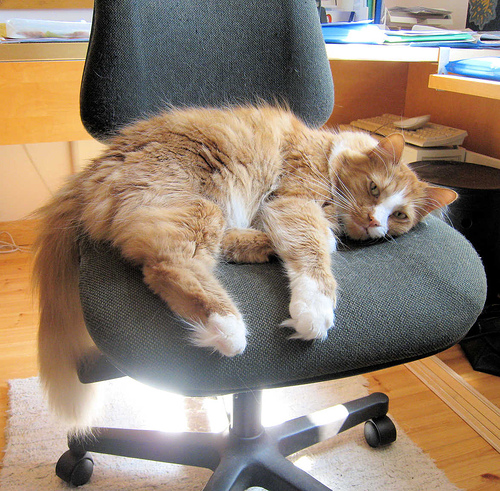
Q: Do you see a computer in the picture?
A: Yes, there is a computer.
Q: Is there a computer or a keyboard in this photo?
A: Yes, there is a computer.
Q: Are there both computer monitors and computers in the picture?
A: No, there is a computer but no computer monitors.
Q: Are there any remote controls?
A: No, there are no remote controls.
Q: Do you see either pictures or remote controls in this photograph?
A: No, there are no remote controls or pictures.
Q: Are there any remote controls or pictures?
A: No, there are no remote controls or pictures.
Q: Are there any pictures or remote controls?
A: No, there are no remote controls or pictures.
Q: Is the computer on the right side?
A: Yes, the computer is on the right of the image.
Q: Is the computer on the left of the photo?
A: No, the computer is on the right of the image.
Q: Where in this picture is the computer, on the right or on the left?
A: The computer is on the right of the image.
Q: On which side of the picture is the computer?
A: The computer is on the right of the image.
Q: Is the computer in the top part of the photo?
A: Yes, the computer is in the top of the image.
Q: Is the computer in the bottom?
A: No, the computer is in the top of the image.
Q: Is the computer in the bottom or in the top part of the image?
A: The computer is in the top of the image.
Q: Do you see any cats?
A: Yes, there is a cat.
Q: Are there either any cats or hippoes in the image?
A: Yes, there is a cat.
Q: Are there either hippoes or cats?
A: Yes, there is a cat.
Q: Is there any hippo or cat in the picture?
A: Yes, there is a cat.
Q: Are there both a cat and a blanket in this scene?
A: No, there is a cat but no blankets.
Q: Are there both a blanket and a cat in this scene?
A: No, there is a cat but no blankets.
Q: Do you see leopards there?
A: No, there are no leopards.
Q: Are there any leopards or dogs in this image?
A: No, there are no leopards or dogs.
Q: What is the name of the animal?
A: The animal is a cat.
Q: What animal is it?
A: The animal is a cat.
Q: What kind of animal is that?
A: This is a cat.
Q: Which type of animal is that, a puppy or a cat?
A: This is a cat.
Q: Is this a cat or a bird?
A: This is a cat.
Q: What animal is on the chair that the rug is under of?
A: The cat is on the chair.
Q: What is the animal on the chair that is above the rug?
A: The animal is a cat.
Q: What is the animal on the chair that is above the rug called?
A: The animal is a cat.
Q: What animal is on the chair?
A: The animal is a cat.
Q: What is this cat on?
A: The cat is on the chair.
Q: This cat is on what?
A: The cat is on the chair.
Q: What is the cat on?
A: The cat is on the chair.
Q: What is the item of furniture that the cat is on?
A: The piece of furniture is a chair.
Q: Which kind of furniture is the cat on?
A: The cat is on the chair.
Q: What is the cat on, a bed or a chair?
A: The cat is on a chair.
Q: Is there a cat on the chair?
A: Yes, there is a cat on the chair.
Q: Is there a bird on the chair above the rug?
A: No, there is a cat on the chair.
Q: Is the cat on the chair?
A: Yes, the cat is on the chair.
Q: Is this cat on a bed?
A: No, the cat is on the chair.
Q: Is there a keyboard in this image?
A: Yes, there is a keyboard.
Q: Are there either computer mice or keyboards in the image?
A: Yes, there is a keyboard.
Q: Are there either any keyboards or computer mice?
A: Yes, there is a keyboard.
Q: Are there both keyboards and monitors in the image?
A: No, there is a keyboard but no monitors.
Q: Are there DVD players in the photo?
A: No, there are no DVD players.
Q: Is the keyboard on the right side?
A: Yes, the keyboard is on the right of the image.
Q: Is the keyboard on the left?
A: No, the keyboard is on the right of the image.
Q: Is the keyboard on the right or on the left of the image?
A: The keyboard is on the right of the image.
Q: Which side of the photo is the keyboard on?
A: The keyboard is on the right of the image.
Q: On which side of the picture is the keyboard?
A: The keyboard is on the right of the image.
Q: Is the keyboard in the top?
A: Yes, the keyboard is in the top of the image.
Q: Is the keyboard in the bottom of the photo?
A: No, the keyboard is in the top of the image.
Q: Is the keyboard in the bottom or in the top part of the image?
A: The keyboard is in the top of the image.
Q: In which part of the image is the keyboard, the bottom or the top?
A: The keyboard is in the top of the image.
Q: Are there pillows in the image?
A: No, there are no pillows.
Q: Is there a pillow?
A: No, there are no pillows.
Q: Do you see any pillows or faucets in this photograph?
A: No, there are no pillows or faucets.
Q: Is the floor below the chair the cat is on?
A: Yes, the floor is below the chair.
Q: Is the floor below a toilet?
A: No, the floor is below the chair.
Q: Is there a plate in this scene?
A: No, there are no plates.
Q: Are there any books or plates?
A: No, there are no plates or books.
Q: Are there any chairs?
A: Yes, there is a chair.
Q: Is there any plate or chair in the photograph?
A: Yes, there is a chair.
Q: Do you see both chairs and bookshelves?
A: No, there is a chair but no bookshelves.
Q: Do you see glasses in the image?
A: No, there are no glasses.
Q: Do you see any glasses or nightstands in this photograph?
A: No, there are no glasses or nightstands.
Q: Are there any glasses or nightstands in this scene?
A: No, there are no glasses or nightstands.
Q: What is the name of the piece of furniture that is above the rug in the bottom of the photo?
A: The piece of furniture is a chair.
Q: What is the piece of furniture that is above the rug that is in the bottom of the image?
A: The piece of furniture is a chair.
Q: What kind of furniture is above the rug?
A: The piece of furniture is a chair.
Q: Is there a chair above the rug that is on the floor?
A: Yes, there is a chair above the rug.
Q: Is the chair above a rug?
A: Yes, the chair is above a rug.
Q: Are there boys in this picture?
A: No, there are no boys.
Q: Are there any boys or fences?
A: No, there are no boys or fences.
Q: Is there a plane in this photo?
A: No, there are no airplanes.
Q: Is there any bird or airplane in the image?
A: No, there are no airplanes or birds.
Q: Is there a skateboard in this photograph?
A: No, there are no skateboards.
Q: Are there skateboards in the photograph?
A: No, there are no skateboards.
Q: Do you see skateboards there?
A: No, there are no skateboards.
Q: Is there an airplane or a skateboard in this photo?
A: No, there are no skateboards or airplanes.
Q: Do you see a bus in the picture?
A: No, there are no buses.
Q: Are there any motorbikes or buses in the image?
A: No, there are no buses or motorbikes.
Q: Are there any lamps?
A: No, there are no lamps.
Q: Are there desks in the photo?
A: Yes, there is a desk.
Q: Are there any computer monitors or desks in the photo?
A: Yes, there is a desk.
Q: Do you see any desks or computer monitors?
A: Yes, there is a desk.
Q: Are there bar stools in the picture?
A: No, there are no bar stools.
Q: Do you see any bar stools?
A: No, there are no bar stools.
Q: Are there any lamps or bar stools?
A: No, there are no bar stools or lamps.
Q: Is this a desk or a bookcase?
A: This is a desk.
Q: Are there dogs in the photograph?
A: No, there are no dogs.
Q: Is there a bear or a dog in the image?
A: No, there are no dogs or bears.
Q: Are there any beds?
A: No, there are no beds.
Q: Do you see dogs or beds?
A: No, there are no beds or dogs.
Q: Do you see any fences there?
A: No, there are no fences.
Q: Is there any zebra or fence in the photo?
A: No, there are no fences or zebras.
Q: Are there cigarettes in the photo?
A: No, there are no cigarettes.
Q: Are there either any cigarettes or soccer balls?
A: No, there are no cigarettes or soccer balls.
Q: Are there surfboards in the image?
A: No, there are no surfboards.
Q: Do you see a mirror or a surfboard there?
A: No, there are no surfboards or mirrors.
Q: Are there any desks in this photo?
A: Yes, there is a desk.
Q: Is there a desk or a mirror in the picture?
A: Yes, there is a desk.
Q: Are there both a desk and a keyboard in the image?
A: Yes, there are both a desk and a keyboard.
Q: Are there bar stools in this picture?
A: No, there are no bar stools.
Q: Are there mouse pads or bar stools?
A: No, there are no bar stools or mouse pads.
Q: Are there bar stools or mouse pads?
A: No, there are no bar stools or mouse pads.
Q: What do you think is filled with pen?
A: The desk is filled with pen.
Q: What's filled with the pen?
A: The desk is filled with pen.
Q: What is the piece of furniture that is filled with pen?
A: The piece of furniture is a desk.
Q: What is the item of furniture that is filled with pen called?
A: The piece of furniture is a desk.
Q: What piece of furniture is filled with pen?
A: The piece of furniture is a desk.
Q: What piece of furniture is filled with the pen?
A: The piece of furniture is a desk.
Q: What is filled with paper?
A: The desk is filled with paper.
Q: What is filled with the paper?
A: The desk is filled with paper.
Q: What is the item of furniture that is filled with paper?
A: The piece of furniture is a desk.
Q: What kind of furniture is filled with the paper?
A: The piece of furniture is a desk.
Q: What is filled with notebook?
A: The desk is filled with notebook.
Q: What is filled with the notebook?
A: The desk is filled with notebook.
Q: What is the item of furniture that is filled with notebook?
A: The piece of furniture is a desk.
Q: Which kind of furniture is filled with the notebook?
A: The piece of furniture is a desk.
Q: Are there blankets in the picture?
A: No, there are no blankets.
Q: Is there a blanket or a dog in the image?
A: No, there are no blankets or dogs.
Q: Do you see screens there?
A: No, there are no screens.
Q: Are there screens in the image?
A: No, there are no screens.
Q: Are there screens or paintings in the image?
A: No, there are no screens or paintings.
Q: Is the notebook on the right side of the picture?
A: Yes, the notebook is on the right of the image.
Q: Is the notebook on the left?
A: No, the notebook is on the right of the image.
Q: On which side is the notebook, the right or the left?
A: The notebook is on the right of the image.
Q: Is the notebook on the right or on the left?
A: The notebook is on the right of the image.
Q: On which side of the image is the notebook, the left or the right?
A: The notebook is on the right of the image.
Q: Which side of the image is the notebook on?
A: The notebook is on the right of the image.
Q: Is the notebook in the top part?
A: Yes, the notebook is in the top of the image.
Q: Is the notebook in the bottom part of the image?
A: No, the notebook is in the top of the image.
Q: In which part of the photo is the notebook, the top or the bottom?
A: The notebook is in the top of the image.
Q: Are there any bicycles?
A: No, there are no bicycles.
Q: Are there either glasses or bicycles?
A: No, there are no bicycles or glasses.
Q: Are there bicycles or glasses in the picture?
A: No, there are no bicycles or glasses.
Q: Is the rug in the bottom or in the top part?
A: The rug is in the bottom of the image.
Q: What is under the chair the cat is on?
A: The rug is under the chair.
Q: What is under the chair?
A: The rug is under the chair.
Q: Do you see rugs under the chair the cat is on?
A: Yes, there is a rug under the chair.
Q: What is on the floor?
A: The rug is on the floor.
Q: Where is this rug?
A: The rug is on the floor.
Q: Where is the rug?
A: The rug is on the floor.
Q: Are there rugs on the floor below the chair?
A: Yes, there is a rug on the floor.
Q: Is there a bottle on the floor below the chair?
A: No, there is a rug on the floor.